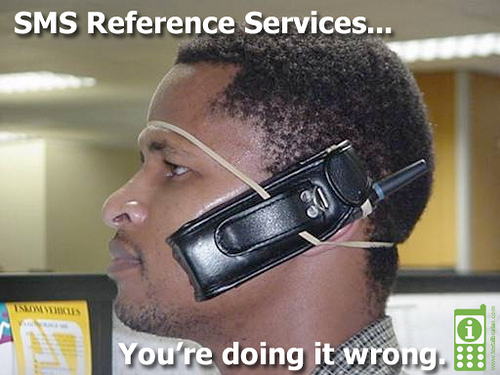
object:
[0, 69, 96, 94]
light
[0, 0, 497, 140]
ceiling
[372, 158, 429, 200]
antenna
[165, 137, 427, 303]
phone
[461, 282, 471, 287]
?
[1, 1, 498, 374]
picture